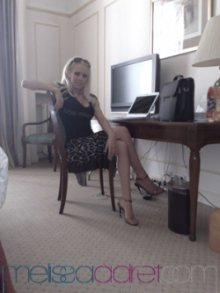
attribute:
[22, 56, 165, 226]
woman — blonde, sitting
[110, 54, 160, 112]
tv — flat screen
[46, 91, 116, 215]
chair — wooden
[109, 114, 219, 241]
table — brown, wooden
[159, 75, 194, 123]
bag — black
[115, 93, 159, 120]
laptop — white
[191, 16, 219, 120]
lamp — partially seen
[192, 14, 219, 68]
shade — white, large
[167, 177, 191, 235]
trash can — black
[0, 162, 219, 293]
carpet — tan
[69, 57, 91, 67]
sunglasses — black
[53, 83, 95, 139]
tank top — black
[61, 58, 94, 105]
hair — long, blonde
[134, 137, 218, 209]
wires — electric cords